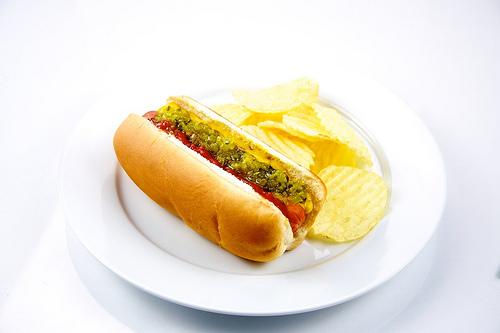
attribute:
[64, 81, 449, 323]
plate — white, round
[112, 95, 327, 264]
hotdog — brown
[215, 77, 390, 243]
chips — ruffled, curved, ridged, crisp, yellow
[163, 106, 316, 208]
relish — green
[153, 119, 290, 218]
ketchup — thin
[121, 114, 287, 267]
bun — white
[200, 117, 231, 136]
mustard — thick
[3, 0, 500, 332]
table — white